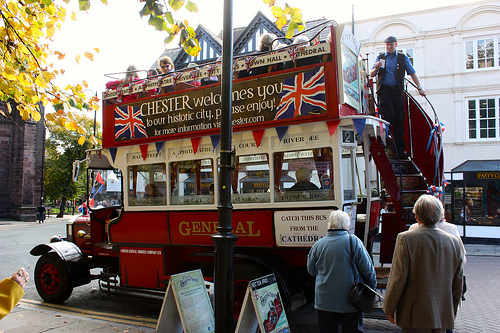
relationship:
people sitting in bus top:
[78, 20, 368, 96] [60, 25, 369, 211]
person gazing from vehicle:
[120, 62, 147, 82] [33, 64, 448, 300]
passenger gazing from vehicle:
[158, 57, 173, 74] [33, 64, 448, 300]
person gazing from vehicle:
[254, 28, 280, 54] [33, 64, 448, 300]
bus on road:
[84, 39, 407, 332] [2, 206, 484, 313]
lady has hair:
[308, 210, 379, 330] [294, 207, 396, 302]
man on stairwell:
[369, 32, 417, 152] [359, 55, 451, 310]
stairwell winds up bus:
[361, 67, 444, 321] [25, 39, 442, 320]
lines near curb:
[1, 294, 163, 330] [0, 277, 164, 331]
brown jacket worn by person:
[380, 225, 467, 329] [381, 195, 468, 331]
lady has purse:
[308, 210, 379, 330] [355, 282, 382, 312]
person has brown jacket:
[376, 189, 475, 331] [388, 225, 467, 329]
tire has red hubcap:
[33, 253, 70, 303] [38, 260, 60, 295]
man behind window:
[284, 165, 317, 198] [272, 145, 336, 199]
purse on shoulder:
[345, 233, 378, 310] [337, 229, 364, 259]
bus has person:
[25, 39, 442, 320] [120, 62, 147, 82]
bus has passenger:
[25, 39, 442, 320] [145, 67, 159, 82]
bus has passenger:
[25, 39, 442, 320] [156, 54, 173, 74]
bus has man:
[25, 39, 442, 320] [288, 167, 320, 190]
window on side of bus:
[272, 148, 333, 203] [25, 39, 442, 320]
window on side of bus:
[221, 151, 270, 198] [25, 39, 442, 320]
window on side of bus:
[166, 157, 218, 206] [25, 39, 442, 320]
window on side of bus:
[125, 165, 167, 206] [25, 39, 442, 320]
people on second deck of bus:
[105, 31, 331, 101] [25, 39, 442, 320]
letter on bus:
[184, 214, 201, 237] [63, 16, 388, 266]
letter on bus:
[229, 218, 249, 248] [29, 0, 408, 318]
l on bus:
[244, 220, 261, 236] [25, 39, 442, 320]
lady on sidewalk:
[308, 210, 379, 330] [2, 303, 160, 331]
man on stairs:
[369, 35, 422, 157] [365, 123, 450, 298]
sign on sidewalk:
[228, 272, 301, 332] [36, 301, 307, 332]